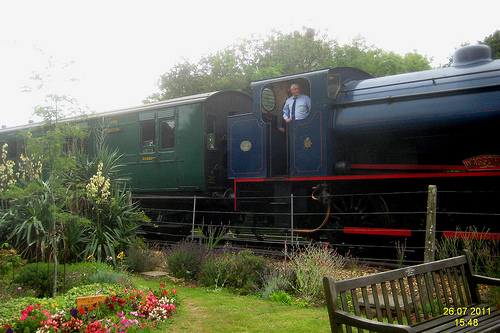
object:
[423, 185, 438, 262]
fence post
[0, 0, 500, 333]
picture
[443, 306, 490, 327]
date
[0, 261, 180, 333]
bed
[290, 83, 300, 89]
hair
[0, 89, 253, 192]
car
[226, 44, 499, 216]
engine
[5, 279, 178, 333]
flower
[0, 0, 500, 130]
grey sky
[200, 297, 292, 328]
grass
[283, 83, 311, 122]
man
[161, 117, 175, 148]
window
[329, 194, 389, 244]
train wheel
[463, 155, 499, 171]
logo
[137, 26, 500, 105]
tree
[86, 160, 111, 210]
flowers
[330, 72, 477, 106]
railing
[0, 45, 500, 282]
train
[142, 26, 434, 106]
leaves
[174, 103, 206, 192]
paint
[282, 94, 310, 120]
shirt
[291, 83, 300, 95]
head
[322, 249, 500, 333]
back